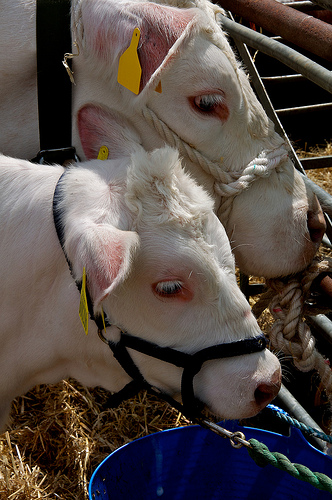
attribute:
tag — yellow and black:
[75, 258, 92, 336]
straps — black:
[109, 325, 271, 404]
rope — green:
[245, 436, 330, 493]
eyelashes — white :
[140, 263, 191, 303]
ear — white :
[71, 100, 152, 170]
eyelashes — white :
[182, 93, 235, 106]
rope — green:
[244, 438, 331, 489]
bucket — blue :
[87, 419, 330, 482]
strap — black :
[51, 167, 270, 422]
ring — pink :
[151, 275, 193, 302]